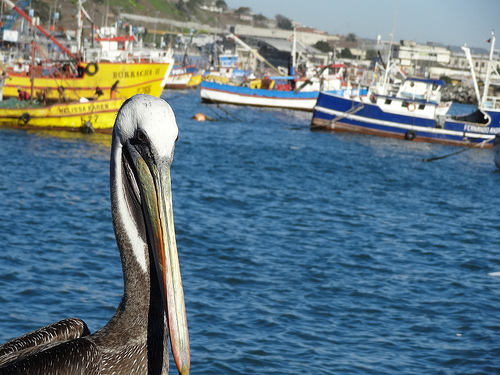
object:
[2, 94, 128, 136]
boat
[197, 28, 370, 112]
boat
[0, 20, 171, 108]
boat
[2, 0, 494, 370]
coastal picture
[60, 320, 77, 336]
feather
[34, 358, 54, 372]
feather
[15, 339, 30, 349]
feather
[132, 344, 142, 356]
feather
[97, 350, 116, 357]
feather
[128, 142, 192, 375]
beak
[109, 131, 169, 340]
neck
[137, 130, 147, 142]
eye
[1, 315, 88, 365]
wing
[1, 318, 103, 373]
back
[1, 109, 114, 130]
paint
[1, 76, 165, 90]
line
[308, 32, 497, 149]
boat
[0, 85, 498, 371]
water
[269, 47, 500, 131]
dock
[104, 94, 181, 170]
head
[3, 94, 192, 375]
bird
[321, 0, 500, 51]
sky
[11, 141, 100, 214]
sea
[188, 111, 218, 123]
buoy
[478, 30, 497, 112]
pole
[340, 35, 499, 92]
building